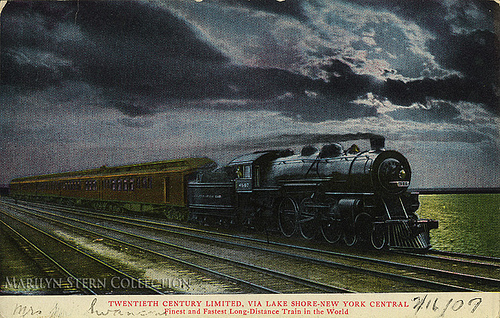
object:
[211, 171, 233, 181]
side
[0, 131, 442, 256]
train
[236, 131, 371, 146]
smoke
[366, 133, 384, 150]
chimney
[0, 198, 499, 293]
line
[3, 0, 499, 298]
painting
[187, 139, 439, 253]
engine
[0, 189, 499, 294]
ground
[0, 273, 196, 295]
name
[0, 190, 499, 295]
rail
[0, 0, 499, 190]
sky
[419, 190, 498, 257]
field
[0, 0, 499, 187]
cloud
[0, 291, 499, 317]
card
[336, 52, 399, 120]
reflection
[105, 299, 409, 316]
words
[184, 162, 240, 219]
coal bin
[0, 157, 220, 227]
train cars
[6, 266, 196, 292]
wording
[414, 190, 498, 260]
grass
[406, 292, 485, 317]
date stamp